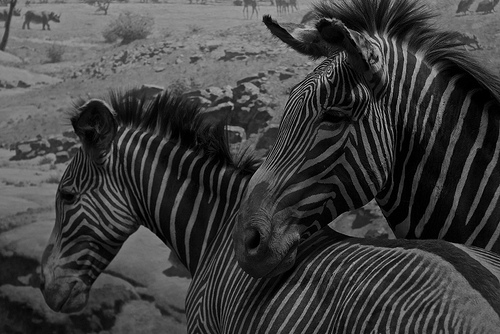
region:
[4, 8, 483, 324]
Picture is taken in black and white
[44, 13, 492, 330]
There are two zebras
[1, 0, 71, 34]
Animals in the top left corner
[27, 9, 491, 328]
You can only see the left side of the zebras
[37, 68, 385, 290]
The zebras are looking to the left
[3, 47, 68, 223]
The ground is covered in dirt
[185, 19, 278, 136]
There are rocks on the ground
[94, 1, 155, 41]
A small bush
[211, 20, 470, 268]
This zebra's head is on top of the other zebra's body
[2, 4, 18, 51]
A narrow tree trunk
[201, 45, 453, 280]
the head of a zebra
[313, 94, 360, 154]
the eye of a zebra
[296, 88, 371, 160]
the round eye of a zebra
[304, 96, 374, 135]
the black eye of a zebra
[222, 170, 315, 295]
the nose of a zebra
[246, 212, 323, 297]
the mouth of a zebra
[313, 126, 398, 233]
the jaw of a zebra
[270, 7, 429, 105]
the ears of a zebra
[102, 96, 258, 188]
the main of a zebra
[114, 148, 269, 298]
the neck of a zebra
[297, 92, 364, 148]
eye of the zebra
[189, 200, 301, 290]
nose of the zebra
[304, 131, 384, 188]
black and white stripes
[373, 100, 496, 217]
neck of the zebra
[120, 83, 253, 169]
back of the zebra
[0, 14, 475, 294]
two zebras in photo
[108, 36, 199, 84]
rocks in the distance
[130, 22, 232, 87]
dirt on the ground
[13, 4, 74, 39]
animal in the distance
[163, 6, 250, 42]
background of the photo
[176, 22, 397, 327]
zebra head over body of zebra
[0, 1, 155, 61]
four-legged animals walking toward a bush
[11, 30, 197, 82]
pile of rocks on sloped ground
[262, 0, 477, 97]
bushy mane behind animal's ears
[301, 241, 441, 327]
thin light stripes over dark background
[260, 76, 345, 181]
long thin stripes to side of zebra's eye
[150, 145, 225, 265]
short stripe between long stripes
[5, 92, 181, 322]
profile of animal's head against flat rocks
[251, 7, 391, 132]
dark ears slanted forward above eye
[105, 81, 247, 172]
black hairs of mane standing straight up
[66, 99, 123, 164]
ear of a zebra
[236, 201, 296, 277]
nose and nostril of a zebra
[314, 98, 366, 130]
eye of a zebra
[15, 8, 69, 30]
a rhino behind the zebras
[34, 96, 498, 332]
a zebra in the field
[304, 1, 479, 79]
hair on a zebra's head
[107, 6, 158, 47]
a bush on the ground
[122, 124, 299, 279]
neck of a zebra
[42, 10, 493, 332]
two zebras in a field together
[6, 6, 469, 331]
rocky, dirty ground